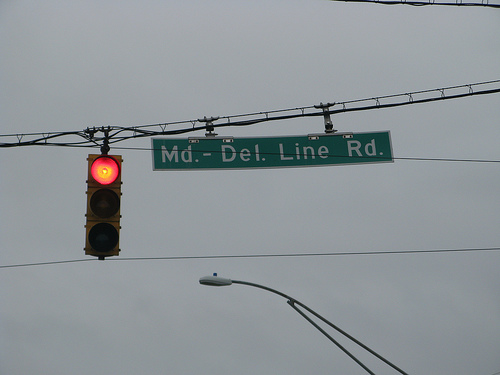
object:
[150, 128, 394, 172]
street sign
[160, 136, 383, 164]
lettering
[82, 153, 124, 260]
traffic signal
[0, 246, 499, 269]
power line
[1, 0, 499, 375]
sky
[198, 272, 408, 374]
street lamp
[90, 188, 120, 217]
bulb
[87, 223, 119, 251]
bulb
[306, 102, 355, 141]
bracket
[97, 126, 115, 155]
bracket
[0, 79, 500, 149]
wire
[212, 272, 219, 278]
light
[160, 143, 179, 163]
letter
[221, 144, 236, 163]
letter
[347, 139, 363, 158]
letter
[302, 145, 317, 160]
letter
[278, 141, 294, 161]
letter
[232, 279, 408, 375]
pole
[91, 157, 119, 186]
light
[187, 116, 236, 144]
bracket